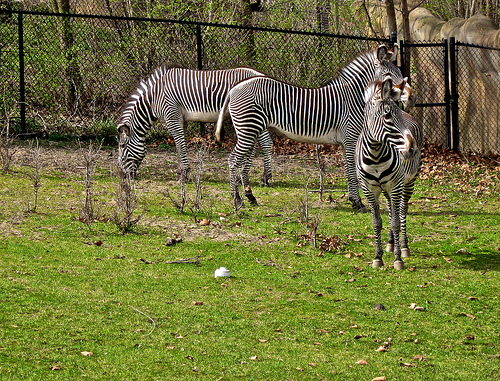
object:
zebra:
[353, 78, 424, 269]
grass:
[0, 172, 500, 381]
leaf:
[354, 358, 370, 366]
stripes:
[285, 84, 291, 124]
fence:
[0, 8, 500, 156]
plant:
[106, 128, 152, 231]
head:
[363, 73, 432, 168]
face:
[371, 98, 418, 160]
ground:
[0, 126, 499, 380]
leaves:
[452, 154, 461, 159]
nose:
[404, 133, 418, 159]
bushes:
[8, 136, 55, 213]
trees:
[55, 0, 76, 112]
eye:
[383, 112, 392, 121]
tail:
[215, 93, 231, 142]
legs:
[160, 112, 191, 184]